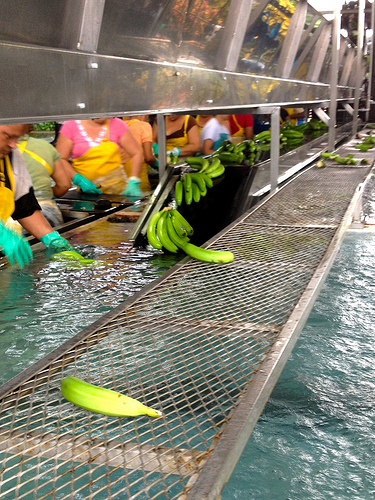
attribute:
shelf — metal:
[1, 127, 373, 499]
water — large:
[3, 223, 373, 497]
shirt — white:
[57, 118, 124, 156]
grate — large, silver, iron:
[154, 287, 238, 384]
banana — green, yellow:
[143, 207, 236, 262]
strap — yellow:
[15, 140, 56, 174]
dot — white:
[75, 119, 82, 124]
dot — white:
[78, 123, 84, 128]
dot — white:
[81, 131, 87, 135]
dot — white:
[85, 137, 93, 141]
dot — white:
[100, 130, 106, 135]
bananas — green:
[141, 141, 257, 265]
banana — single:
[180, 244, 235, 263]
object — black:
[125, 378, 334, 438]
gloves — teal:
[2, 217, 70, 270]